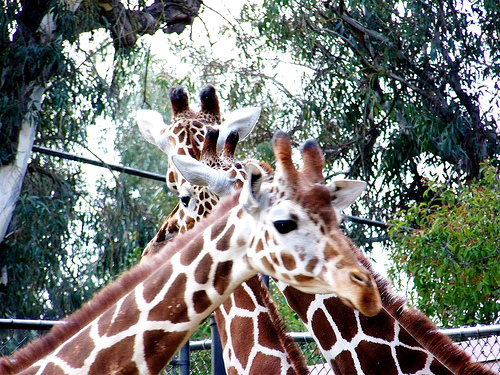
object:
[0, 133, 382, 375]
giraffe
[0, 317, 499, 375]
fence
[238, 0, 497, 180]
trees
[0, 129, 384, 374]
markings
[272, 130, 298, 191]
horns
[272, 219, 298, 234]
eye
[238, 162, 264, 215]
ear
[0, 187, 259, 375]
neck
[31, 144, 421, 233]
bar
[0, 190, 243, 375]
mane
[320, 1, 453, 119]
branches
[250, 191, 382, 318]
face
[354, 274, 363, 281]
nostril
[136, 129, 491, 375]
giraffes